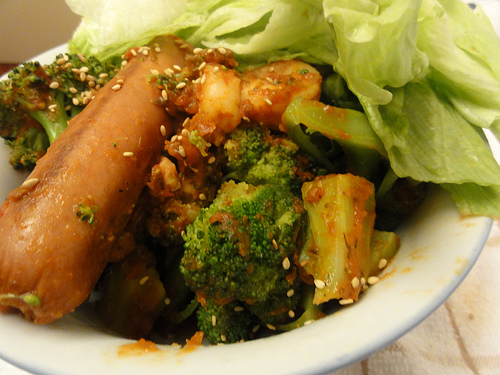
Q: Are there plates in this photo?
A: Yes, there is a plate.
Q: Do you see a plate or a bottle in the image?
A: Yes, there is a plate.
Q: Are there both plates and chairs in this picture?
A: No, there is a plate but no chairs.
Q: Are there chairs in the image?
A: No, there are no chairs.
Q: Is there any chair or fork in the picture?
A: No, there are no chairs or forks.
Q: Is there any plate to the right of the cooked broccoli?
A: Yes, there is a plate to the right of the broccoli.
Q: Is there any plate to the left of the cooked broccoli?
A: No, the plate is to the right of the broccoli.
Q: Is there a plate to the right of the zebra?
A: Yes, there is a plate to the right of the zebra.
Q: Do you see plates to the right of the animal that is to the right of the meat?
A: Yes, there is a plate to the right of the zebra.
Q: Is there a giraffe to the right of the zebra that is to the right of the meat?
A: No, there is a plate to the right of the zebra.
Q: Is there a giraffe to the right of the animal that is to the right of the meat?
A: No, there is a plate to the right of the zebra.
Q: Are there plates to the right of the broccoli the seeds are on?
A: Yes, there is a plate to the right of the broccoli.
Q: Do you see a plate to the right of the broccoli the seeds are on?
A: Yes, there is a plate to the right of the broccoli.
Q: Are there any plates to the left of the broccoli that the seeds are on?
A: No, the plate is to the right of the broccoli.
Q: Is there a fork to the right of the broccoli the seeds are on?
A: No, there is a plate to the right of the broccoli.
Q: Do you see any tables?
A: Yes, there is a table.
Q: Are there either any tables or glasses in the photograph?
A: Yes, there is a table.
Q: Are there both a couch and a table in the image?
A: No, there is a table but no couches.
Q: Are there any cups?
A: No, there are no cups.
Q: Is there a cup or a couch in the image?
A: No, there are no cups or couches.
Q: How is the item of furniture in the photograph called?
A: The piece of furniture is a table.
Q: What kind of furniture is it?
A: The piece of furniture is a table.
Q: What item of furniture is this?
A: That is a table.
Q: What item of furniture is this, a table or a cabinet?
A: That is a table.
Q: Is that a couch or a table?
A: That is a table.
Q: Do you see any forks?
A: No, there are no forks.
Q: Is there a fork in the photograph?
A: No, there are no forks.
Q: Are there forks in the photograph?
A: No, there are no forks.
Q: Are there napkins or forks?
A: No, there are no forks or napkins.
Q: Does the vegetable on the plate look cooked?
A: Yes, the vegetable is cooked.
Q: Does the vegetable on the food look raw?
A: No, the vegetable is cooked.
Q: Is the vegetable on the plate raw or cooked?
A: The vegetable is cooked.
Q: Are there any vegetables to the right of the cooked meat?
A: Yes, there is a vegetable to the right of the meat.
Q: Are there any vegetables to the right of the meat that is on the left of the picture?
A: Yes, there is a vegetable to the right of the meat.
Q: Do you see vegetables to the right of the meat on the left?
A: Yes, there is a vegetable to the right of the meat.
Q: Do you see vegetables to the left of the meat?
A: No, the vegetable is to the right of the meat.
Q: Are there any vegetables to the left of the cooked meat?
A: No, the vegetable is to the right of the meat.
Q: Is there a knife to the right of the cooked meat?
A: No, there is a vegetable to the right of the meat.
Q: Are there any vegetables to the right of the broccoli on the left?
A: Yes, there is a vegetable to the right of the broccoli.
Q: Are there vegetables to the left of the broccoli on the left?
A: No, the vegetable is to the right of the broccoli.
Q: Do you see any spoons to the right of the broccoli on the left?
A: No, there is a vegetable to the right of the broccoli.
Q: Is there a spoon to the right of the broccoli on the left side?
A: No, there is a vegetable to the right of the broccoli.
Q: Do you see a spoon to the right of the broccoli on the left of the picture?
A: No, there is a vegetable to the right of the broccoli.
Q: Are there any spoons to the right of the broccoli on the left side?
A: No, there is a vegetable to the right of the broccoli.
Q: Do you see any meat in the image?
A: Yes, there is meat.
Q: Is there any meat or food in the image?
A: Yes, there is meat.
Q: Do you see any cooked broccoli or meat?
A: Yes, there is cooked meat.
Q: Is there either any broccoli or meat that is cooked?
A: Yes, the meat is cooked.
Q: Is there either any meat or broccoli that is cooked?
A: Yes, the meat is cooked.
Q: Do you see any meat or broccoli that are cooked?
A: Yes, the meat is cooked.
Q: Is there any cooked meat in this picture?
A: Yes, there is cooked meat.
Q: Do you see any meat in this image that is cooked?
A: Yes, there is meat that is cooked.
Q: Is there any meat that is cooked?
A: Yes, there is meat that is cooked.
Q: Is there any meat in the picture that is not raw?
A: Yes, there is cooked meat.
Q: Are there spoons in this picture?
A: No, there are no spoons.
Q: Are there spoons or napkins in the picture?
A: No, there are no spoons or napkins.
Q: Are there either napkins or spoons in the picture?
A: No, there are no spoons or napkins.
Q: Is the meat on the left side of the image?
A: Yes, the meat is on the left of the image.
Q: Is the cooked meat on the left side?
A: Yes, the meat is on the left of the image.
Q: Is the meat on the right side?
A: No, the meat is on the left of the image.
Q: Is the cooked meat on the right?
A: No, the meat is on the left of the image.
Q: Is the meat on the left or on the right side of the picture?
A: The meat is on the left of the image.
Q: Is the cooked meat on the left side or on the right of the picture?
A: The meat is on the left of the image.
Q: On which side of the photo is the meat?
A: The meat is on the left of the image.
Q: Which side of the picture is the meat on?
A: The meat is on the left of the image.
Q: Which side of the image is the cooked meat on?
A: The meat is on the left of the image.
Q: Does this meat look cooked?
A: Yes, the meat is cooked.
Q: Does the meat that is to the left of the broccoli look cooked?
A: Yes, the meat is cooked.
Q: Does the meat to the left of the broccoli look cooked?
A: Yes, the meat is cooked.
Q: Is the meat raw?
A: No, the meat is cooked.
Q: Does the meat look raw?
A: No, the meat is cooked.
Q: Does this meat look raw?
A: No, the meat is cooked.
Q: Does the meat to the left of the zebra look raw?
A: No, the meat is cooked.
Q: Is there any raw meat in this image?
A: No, there is meat but it is cooked.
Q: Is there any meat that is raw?
A: No, there is meat but it is cooked.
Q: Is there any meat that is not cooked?
A: No, there is meat but it is cooked.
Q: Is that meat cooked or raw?
A: The meat is cooked.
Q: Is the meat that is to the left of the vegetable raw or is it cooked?
A: The meat is cooked.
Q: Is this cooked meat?
A: Yes, this is cooked meat.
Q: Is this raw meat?
A: No, this is cooked meat.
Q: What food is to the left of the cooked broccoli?
A: The food is meat.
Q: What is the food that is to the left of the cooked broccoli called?
A: The food is meat.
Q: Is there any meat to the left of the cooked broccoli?
A: Yes, there is meat to the left of the broccoli.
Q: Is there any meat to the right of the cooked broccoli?
A: No, the meat is to the left of the broccoli.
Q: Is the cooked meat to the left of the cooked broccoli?
A: Yes, the meat is to the left of the broccoli.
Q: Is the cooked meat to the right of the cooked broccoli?
A: No, the meat is to the left of the broccoli.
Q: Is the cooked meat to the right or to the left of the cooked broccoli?
A: The meat is to the left of the broccoli.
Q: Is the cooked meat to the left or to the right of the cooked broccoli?
A: The meat is to the left of the broccoli.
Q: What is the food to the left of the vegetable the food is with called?
A: The food is meat.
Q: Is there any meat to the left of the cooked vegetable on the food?
A: Yes, there is meat to the left of the vegetable.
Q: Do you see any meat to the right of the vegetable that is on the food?
A: No, the meat is to the left of the vegetable.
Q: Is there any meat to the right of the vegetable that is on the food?
A: No, the meat is to the left of the vegetable.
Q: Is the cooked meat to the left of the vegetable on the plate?
A: Yes, the meat is to the left of the vegetable.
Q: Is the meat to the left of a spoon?
A: No, the meat is to the left of the vegetable.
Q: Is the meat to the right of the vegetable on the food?
A: No, the meat is to the left of the vegetable.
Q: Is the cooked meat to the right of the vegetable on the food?
A: No, the meat is to the left of the vegetable.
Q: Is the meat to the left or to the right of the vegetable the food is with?
A: The meat is to the left of the vegetable.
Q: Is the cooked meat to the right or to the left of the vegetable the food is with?
A: The meat is to the left of the vegetable.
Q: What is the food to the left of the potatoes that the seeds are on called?
A: The food is meat.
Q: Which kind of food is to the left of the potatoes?
A: The food is meat.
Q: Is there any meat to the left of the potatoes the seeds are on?
A: Yes, there is meat to the left of the potatoes.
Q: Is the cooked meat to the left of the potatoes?
A: Yes, the meat is to the left of the potatoes.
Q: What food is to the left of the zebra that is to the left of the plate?
A: The food is meat.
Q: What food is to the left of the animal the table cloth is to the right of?
A: The food is meat.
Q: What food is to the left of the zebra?
A: The food is meat.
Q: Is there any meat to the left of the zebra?
A: Yes, there is meat to the left of the zebra.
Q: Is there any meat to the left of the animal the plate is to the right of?
A: Yes, there is meat to the left of the zebra.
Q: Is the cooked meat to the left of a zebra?
A: Yes, the meat is to the left of a zebra.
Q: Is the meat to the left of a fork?
A: No, the meat is to the left of a zebra.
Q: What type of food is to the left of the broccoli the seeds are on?
A: The food is meat.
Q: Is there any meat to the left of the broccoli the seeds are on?
A: Yes, there is meat to the left of the broccoli.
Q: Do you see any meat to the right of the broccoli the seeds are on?
A: No, the meat is to the left of the broccoli.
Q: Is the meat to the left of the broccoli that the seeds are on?
A: Yes, the meat is to the left of the broccoli.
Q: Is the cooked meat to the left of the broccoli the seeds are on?
A: Yes, the meat is to the left of the broccoli.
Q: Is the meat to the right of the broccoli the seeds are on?
A: No, the meat is to the left of the broccoli.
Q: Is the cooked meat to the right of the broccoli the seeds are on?
A: No, the meat is to the left of the broccoli.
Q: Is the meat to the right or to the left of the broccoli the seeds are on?
A: The meat is to the left of the broccoli.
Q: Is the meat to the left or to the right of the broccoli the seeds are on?
A: The meat is to the left of the broccoli.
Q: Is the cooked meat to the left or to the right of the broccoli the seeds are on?
A: The meat is to the left of the broccoli.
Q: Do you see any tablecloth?
A: Yes, there is a tablecloth.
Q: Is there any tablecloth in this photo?
A: Yes, there is a tablecloth.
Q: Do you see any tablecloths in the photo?
A: Yes, there is a tablecloth.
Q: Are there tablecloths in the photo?
A: Yes, there is a tablecloth.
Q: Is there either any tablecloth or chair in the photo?
A: Yes, there is a tablecloth.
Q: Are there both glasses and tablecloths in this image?
A: No, there is a tablecloth but no glasses.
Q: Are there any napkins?
A: No, there are no napkins.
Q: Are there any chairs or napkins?
A: No, there are no napkins or chairs.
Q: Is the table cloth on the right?
A: Yes, the table cloth is on the right of the image.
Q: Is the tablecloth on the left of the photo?
A: No, the tablecloth is on the right of the image.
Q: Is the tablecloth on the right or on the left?
A: The tablecloth is on the right of the image.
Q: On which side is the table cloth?
A: The table cloth is on the right of the image.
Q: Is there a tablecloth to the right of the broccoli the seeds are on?
A: Yes, there is a tablecloth to the right of the broccoli.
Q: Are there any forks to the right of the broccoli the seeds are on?
A: No, there is a tablecloth to the right of the broccoli.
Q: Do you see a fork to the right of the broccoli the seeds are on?
A: No, there is a tablecloth to the right of the broccoli.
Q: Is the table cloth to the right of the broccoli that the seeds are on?
A: Yes, the table cloth is to the right of the broccoli.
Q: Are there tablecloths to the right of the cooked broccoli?
A: Yes, there is a tablecloth to the right of the broccoli.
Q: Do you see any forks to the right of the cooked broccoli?
A: No, there is a tablecloth to the right of the broccoli.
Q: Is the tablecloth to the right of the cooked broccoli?
A: Yes, the tablecloth is to the right of the broccoli.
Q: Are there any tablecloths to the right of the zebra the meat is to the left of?
A: Yes, there is a tablecloth to the right of the zebra.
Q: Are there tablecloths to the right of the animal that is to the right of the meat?
A: Yes, there is a tablecloth to the right of the zebra.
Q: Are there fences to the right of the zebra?
A: No, there is a tablecloth to the right of the zebra.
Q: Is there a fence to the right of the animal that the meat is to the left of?
A: No, there is a tablecloth to the right of the zebra.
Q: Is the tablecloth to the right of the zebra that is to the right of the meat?
A: Yes, the tablecloth is to the right of the zebra.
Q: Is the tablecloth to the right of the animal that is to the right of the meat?
A: Yes, the tablecloth is to the right of the zebra.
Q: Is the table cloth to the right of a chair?
A: No, the table cloth is to the right of the zebra.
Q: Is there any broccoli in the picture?
A: Yes, there is broccoli.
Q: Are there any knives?
A: No, there are no knives.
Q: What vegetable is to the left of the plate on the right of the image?
A: The vegetable is broccoli.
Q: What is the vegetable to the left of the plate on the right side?
A: The vegetable is broccoli.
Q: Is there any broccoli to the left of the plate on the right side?
A: Yes, there is broccoli to the left of the plate.